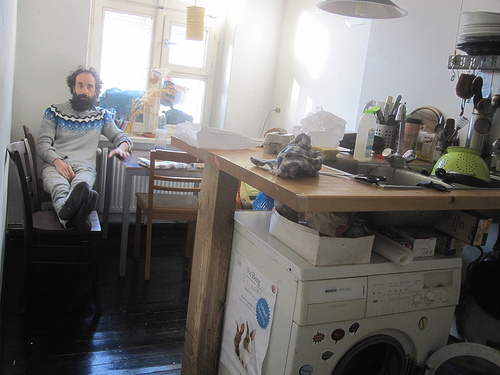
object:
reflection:
[69, 295, 179, 375]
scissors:
[318, 171, 387, 186]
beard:
[70, 93, 96, 112]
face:
[75, 72, 96, 104]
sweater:
[35, 98, 134, 169]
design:
[44, 103, 117, 132]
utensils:
[362, 95, 408, 158]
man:
[36, 65, 134, 234]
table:
[102, 148, 204, 277]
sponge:
[309, 146, 339, 162]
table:
[170, 93, 500, 317]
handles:
[354, 172, 386, 185]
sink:
[323, 161, 454, 190]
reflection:
[292, 12, 372, 132]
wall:
[267, 4, 489, 174]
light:
[317, 0, 408, 20]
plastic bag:
[174, 119, 264, 149]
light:
[185, 4, 205, 41]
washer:
[220, 209, 500, 375]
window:
[90, 2, 237, 145]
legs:
[39, 167, 99, 207]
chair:
[6, 138, 102, 315]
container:
[371, 120, 400, 153]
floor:
[0, 220, 198, 375]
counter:
[172, 134, 500, 375]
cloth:
[250, 133, 325, 177]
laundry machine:
[219, 211, 463, 374]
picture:
[231, 320, 258, 374]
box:
[268, 206, 376, 266]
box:
[391, 228, 438, 258]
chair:
[133, 148, 205, 280]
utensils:
[430, 146, 490, 187]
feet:
[58, 180, 100, 227]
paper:
[218, 250, 279, 374]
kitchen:
[0, 56, 499, 375]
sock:
[58, 181, 90, 221]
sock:
[70, 190, 100, 232]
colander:
[431, 146, 492, 187]